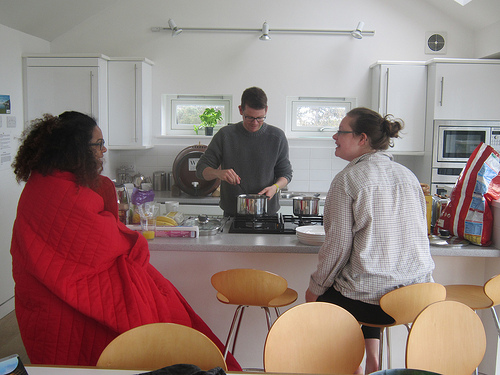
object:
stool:
[263, 302, 366, 375]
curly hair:
[11, 110, 104, 193]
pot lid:
[178, 214, 226, 236]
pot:
[237, 194, 267, 218]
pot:
[293, 193, 321, 217]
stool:
[405, 300, 487, 375]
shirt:
[195, 121, 293, 219]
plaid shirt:
[308, 150, 436, 305]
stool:
[357, 282, 446, 371]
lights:
[151, 18, 375, 41]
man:
[195, 86, 293, 217]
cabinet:
[21, 52, 155, 151]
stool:
[209, 267, 298, 361]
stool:
[442, 274, 499, 375]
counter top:
[146, 232, 500, 257]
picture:
[196, 86, 293, 217]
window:
[160, 94, 234, 139]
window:
[284, 96, 358, 141]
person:
[305, 107, 436, 375]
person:
[195, 86, 293, 216]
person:
[10, 110, 243, 371]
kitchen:
[0, 0, 500, 299]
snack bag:
[435, 137, 498, 249]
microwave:
[430, 118, 500, 195]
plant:
[193, 108, 223, 135]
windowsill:
[166, 134, 213, 139]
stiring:
[236, 184, 270, 218]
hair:
[241, 86, 268, 112]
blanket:
[9, 167, 243, 372]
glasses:
[337, 130, 364, 136]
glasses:
[241, 107, 266, 122]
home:
[0, 0, 500, 375]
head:
[241, 86, 268, 133]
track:
[151, 19, 376, 41]